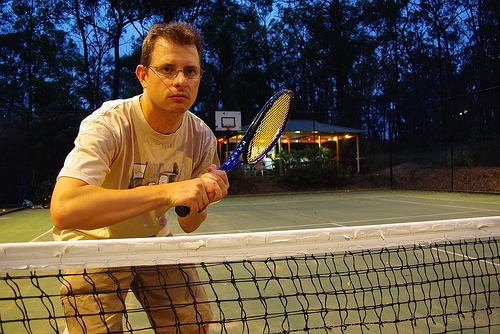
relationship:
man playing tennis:
[47, 21, 231, 333] [0, 184, 498, 332]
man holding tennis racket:
[47, 21, 231, 333] [176, 87, 295, 217]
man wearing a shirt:
[47, 21, 231, 333] [53, 93, 221, 240]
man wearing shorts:
[47, 21, 231, 333] [62, 237, 213, 333]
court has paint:
[18, 190, 499, 333] [29, 222, 57, 244]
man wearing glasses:
[47, 21, 231, 333] [148, 63, 205, 79]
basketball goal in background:
[214, 108, 243, 161] [1, 0, 500, 196]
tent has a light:
[221, 119, 366, 180] [344, 132, 352, 139]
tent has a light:
[221, 119, 366, 180] [333, 134, 341, 140]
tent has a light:
[221, 119, 366, 180] [281, 138, 289, 143]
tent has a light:
[221, 119, 366, 180] [238, 135, 243, 139]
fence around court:
[361, 144, 499, 194] [18, 190, 499, 333]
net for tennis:
[0, 216, 500, 333] [0, 184, 498, 332]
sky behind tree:
[6, 1, 496, 69] [95, 2, 136, 98]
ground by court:
[382, 167, 500, 194] [18, 190, 499, 333]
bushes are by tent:
[273, 147, 353, 189] [221, 119, 366, 180]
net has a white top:
[0, 216, 500, 333] [2, 214, 500, 271]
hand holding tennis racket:
[204, 163, 231, 198] [176, 87, 295, 217]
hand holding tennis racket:
[175, 180, 208, 216] [176, 87, 295, 217]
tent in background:
[221, 119, 366, 180] [1, 0, 500, 196]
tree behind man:
[95, 2, 136, 98] [47, 21, 231, 333]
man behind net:
[47, 21, 231, 333] [0, 216, 500, 333]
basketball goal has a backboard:
[214, 108, 243, 161] [214, 108, 243, 133]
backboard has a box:
[214, 108, 243, 133] [220, 115, 237, 128]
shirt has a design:
[53, 93, 221, 240] [131, 161, 178, 190]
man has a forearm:
[47, 21, 231, 333] [50, 182, 167, 230]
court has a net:
[18, 190, 499, 333] [0, 216, 500, 333]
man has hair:
[47, 21, 231, 333] [140, 22, 203, 68]